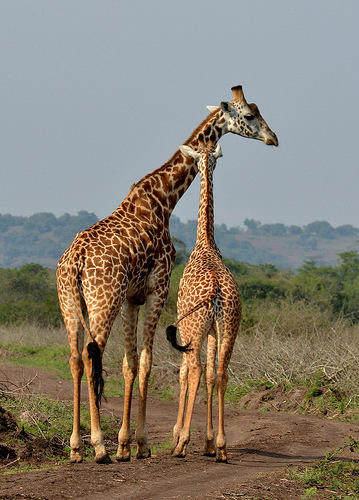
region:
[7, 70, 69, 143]
white clouds in blue sky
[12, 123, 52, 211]
white clouds in blue sky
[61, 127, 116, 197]
white clouds in blue sky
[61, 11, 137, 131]
white clouds in blue sky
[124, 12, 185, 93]
white clouds in blue sky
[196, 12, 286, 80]
white clouds in blue sky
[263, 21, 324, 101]
white clouds in blue sky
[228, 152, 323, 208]
white clouds in blue sky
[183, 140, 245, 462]
giraffe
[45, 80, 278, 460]
two giraffes on the road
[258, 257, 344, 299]
the green foliage behind the giraffes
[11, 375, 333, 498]
the road is unpaved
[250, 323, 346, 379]
the tall grass is dry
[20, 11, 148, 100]
the sky is gray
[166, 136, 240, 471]
the giraffe is an infant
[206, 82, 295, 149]
the head of the giraffe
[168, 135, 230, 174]
the head of the giraffe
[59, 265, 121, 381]
the tail of the giraffe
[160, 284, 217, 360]
the tail of the giraffe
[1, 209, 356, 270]
the trees in the distance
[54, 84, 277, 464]
the two giraffe's standing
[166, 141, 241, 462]
the standing shorter giraffe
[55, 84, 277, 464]
the standing taller giraffe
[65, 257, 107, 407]
the tail on the taller giraffe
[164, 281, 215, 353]
the tail on the shorter giraffe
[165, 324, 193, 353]
the black hair at the end of the tail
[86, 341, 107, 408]
the black hair at the end of the tail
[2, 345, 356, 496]
the dirt on the ground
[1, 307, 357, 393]
the long brown grass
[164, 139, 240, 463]
A very young giraffe in the wild.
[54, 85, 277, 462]
An adult giraffe is in a green wasteland.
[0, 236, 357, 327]
The greenest bush in the wild.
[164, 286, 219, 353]
The tail of a small giraffe.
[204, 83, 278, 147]
The head of an adult giraffe.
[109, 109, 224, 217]
The neck of an adult giraffe.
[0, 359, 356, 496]
A pavement made of dirt only.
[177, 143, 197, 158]
The ear of a small giraffe.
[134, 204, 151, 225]
One brown spot in an adult giraffe.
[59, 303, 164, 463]
The legs of an adult giraffe.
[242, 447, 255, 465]
part of a ground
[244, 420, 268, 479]
part of a shade